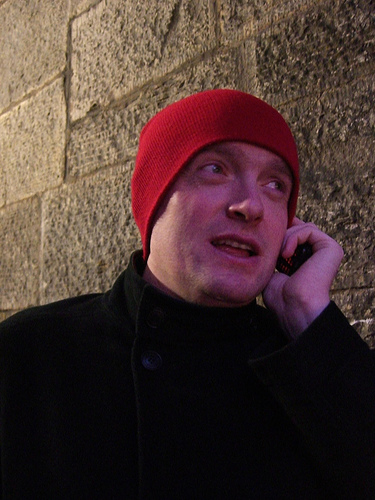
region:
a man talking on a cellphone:
[129, 87, 345, 343]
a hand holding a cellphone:
[261, 213, 346, 330]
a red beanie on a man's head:
[132, 87, 300, 254]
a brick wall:
[0, 3, 110, 285]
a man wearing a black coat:
[2, 86, 373, 485]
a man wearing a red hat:
[129, 88, 305, 320]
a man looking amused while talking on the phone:
[1, 88, 368, 489]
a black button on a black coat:
[141, 348, 163, 369]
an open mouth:
[201, 227, 267, 267]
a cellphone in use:
[275, 231, 313, 275]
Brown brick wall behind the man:
[64, 0, 355, 86]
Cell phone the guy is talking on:
[276, 236, 312, 272]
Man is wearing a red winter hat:
[122, 86, 305, 153]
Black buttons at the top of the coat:
[136, 306, 170, 380]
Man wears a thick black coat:
[11, 309, 368, 495]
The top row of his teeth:
[212, 236, 257, 252]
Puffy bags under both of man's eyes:
[198, 169, 293, 200]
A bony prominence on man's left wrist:
[295, 292, 308, 304]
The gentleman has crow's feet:
[181, 171, 205, 190]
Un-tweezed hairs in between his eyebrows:
[244, 155, 262, 171]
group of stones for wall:
[11, 80, 121, 165]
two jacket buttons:
[131, 290, 162, 413]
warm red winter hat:
[116, 72, 301, 195]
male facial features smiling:
[173, 150, 305, 267]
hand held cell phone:
[276, 213, 314, 284]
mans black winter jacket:
[7, 273, 315, 384]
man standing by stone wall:
[20, 63, 337, 240]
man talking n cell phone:
[201, 222, 280, 277]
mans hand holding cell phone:
[282, 222, 337, 299]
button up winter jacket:
[102, 268, 223, 387]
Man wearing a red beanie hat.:
[130, 83, 302, 306]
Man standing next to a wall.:
[6, 49, 372, 497]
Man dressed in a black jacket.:
[4, 86, 373, 487]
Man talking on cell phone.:
[124, 86, 338, 324]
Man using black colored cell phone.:
[268, 237, 321, 287]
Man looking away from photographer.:
[173, 129, 323, 215]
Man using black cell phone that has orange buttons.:
[271, 229, 328, 297]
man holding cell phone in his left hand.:
[270, 227, 374, 452]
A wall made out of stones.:
[1, 11, 127, 263]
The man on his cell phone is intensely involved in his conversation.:
[145, 116, 344, 312]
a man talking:
[201, 227, 269, 274]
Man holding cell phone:
[259, 221, 331, 286]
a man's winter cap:
[79, 78, 310, 221]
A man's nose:
[226, 168, 266, 221]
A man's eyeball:
[201, 157, 228, 189]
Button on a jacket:
[137, 344, 165, 374]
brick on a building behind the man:
[0, 86, 83, 211]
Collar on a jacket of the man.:
[98, 253, 275, 343]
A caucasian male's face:
[129, 91, 309, 309]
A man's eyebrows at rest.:
[202, 137, 297, 177]